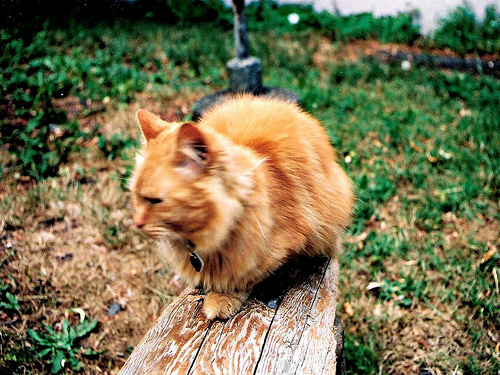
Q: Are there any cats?
A: Yes, there is a cat.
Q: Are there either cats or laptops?
A: Yes, there is a cat.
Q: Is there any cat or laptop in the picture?
A: Yes, there is a cat.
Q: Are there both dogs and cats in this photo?
A: No, there is a cat but no dogs.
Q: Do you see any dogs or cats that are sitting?
A: Yes, the cat is sitting.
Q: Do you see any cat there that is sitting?
A: Yes, there is a cat that is sitting.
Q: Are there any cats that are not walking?
A: Yes, there is a cat that is sitting.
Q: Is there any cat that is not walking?
A: Yes, there is a cat that is sitting.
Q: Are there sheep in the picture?
A: No, there are no sheep.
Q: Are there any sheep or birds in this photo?
A: No, there are no sheep or birds.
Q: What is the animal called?
A: The animal is a cat.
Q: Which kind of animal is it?
A: The animal is a cat.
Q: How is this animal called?
A: That is a cat.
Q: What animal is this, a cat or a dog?
A: That is a cat.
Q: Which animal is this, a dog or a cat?
A: That is a cat.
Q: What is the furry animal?
A: The animal is a cat.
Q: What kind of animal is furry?
A: The animal is a cat.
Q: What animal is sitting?
A: The animal is a cat.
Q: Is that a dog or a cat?
A: That is a cat.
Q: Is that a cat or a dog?
A: That is a cat.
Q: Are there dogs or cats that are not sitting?
A: No, there is a cat but it is sitting.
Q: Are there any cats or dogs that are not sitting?
A: No, there is a cat but it is sitting.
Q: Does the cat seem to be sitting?
A: Yes, the cat is sitting.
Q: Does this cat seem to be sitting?
A: Yes, the cat is sitting.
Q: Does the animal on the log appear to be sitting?
A: Yes, the cat is sitting.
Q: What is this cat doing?
A: The cat is sitting.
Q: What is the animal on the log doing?
A: The cat is sitting.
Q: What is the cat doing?
A: The cat is sitting.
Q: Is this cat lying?
A: No, the cat is sitting.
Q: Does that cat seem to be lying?
A: No, the cat is sitting.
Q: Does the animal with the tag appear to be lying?
A: No, the cat is sitting.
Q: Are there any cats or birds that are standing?
A: No, there is a cat but it is sitting.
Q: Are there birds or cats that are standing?
A: No, there is a cat but it is sitting.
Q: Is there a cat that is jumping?
A: No, there is a cat but it is sitting.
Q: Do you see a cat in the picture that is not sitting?
A: No, there is a cat but it is sitting.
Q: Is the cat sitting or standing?
A: The cat is sitting.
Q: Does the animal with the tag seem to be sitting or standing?
A: The cat is sitting.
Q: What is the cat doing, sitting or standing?
A: The cat is sitting.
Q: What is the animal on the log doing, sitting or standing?
A: The cat is sitting.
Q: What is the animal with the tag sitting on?
A: The cat is sitting on the log.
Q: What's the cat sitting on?
A: The cat is sitting on the log.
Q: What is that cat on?
A: The cat is on the log.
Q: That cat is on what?
A: The cat is on the log.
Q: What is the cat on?
A: The cat is on the log.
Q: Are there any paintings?
A: No, there are no paintings.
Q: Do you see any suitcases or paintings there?
A: No, there are no paintings or suitcases.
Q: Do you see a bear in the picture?
A: No, there are no bears.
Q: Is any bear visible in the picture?
A: No, there are no bears.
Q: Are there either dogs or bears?
A: No, there are no bears or dogs.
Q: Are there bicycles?
A: No, there are no bicycles.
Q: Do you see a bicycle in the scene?
A: No, there are no bicycles.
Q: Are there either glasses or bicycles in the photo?
A: No, there are no bicycles or glasses.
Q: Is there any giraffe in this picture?
A: No, there are no giraffes.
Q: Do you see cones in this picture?
A: No, there are no cones.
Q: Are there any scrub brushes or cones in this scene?
A: No, there are no cones or scrub brushes.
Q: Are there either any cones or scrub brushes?
A: No, there are no cones or scrub brushes.